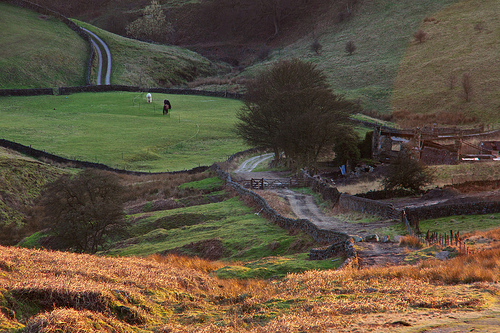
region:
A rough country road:
[220, 139, 398, 263]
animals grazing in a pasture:
[136, 92, 178, 117]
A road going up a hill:
[72, 19, 115, 94]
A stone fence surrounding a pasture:
[1, 82, 401, 177]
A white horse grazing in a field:
[137, 90, 159, 106]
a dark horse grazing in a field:
[157, 98, 172, 118]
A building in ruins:
[356, 117, 476, 173]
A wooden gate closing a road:
[241, 169, 308, 200]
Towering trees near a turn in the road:
[231, 57, 359, 179]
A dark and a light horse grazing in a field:
[141, 91, 173, 116]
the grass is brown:
[41, 258, 123, 310]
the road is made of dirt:
[284, 195, 323, 215]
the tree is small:
[33, 157, 136, 252]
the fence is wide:
[259, 172, 294, 191]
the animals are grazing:
[131, 88, 185, 118]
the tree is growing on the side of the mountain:
[339, 37, 362, 60]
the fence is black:
[28, 147, 80, 165]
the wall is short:
[248, 190, 287, 227]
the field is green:
[92, 114, 204, 146]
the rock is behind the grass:
[435, 241, 462, 260]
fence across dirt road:
[228, 161, 326, 218]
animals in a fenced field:
[0, 79, 226, 179]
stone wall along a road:
[224, 181, 358, 264]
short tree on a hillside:
[343, 38, 363, 59]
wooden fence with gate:
[233, 173, 314, 197]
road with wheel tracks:
[39, 8, 136, 95]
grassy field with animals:
[9, 78, 271, 185]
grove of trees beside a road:
[232, 53, 353, 182]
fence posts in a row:
[402, 221, 489, 263]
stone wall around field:
[340, 160, 498, 232]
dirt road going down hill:
[78, 24, 113, 84]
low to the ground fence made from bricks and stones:
[1, 136, 87, 165]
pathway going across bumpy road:
[264, 184, 347, 225]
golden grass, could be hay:
[1, 248, 178, 311]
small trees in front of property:
[251, 56, 323, 163]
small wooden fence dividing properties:
[238, 175, 313, 188]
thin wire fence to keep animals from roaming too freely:
[136, 88, 201, 144]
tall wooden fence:
[383, 128, 487, 163]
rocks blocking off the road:
[349, 228, 401, 246]